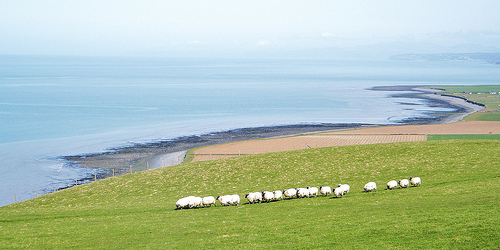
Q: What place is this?
A: It is an ocean.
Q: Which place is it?
A: It is an ocean.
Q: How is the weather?
A: It is cloudy.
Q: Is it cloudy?
A: Yes, it is cloudy.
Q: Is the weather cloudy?
A: Yes, it is cloudy.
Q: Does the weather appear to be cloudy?
A: Yes, it is cloudy.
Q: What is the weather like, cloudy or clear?
A: It is cloudy.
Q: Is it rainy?
A: No, it is cloudy.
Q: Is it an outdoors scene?
A: Yes, it is outdoors.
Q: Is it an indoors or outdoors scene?
A: It is outdoors.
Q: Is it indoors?
A: No, it is outdoors.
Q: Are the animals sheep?
A: Yes, all the animals are sheep.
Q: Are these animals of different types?
A: No, all the animals are sheep.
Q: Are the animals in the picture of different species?
A: No, all the animals are sheep.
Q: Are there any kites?
A: No, there are no kites.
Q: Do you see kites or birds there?
A: No, there are no kites or birds.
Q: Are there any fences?
A: Yes, there is a fence.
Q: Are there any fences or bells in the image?
A: Yes, there is a fence.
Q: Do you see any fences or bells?
A: Yes, there is a fence.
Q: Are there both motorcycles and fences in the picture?
A: No, there is a fence but no motorcycles.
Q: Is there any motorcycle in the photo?
A: No, there are no motorcycles.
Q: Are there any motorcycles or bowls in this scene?
A: No, there are no motorcycles or bowls.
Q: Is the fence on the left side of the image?
A: Yes, the fence is on the left of the image.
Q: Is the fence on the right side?
A: No, the fence is on the left of the image.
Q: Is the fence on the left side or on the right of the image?
A: The fence is on the left of the image.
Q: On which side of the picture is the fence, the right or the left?
A: The fence is on the left of the image.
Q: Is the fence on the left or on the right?
A: The fence is on the left of the image.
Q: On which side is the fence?
A: The fence is on the left of the image.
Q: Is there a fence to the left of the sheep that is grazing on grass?
A: Yes, there is a fence to the left of the sheep.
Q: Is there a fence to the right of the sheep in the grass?
A: No, the fence is to the left of the sheep.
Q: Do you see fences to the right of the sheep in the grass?
A: No, the fence is to the left of the sheep.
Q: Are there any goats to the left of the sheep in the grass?
A: No, there is a fence to the left of the sheep.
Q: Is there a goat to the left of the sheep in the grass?
A: No, there is a fence to the left of the sheep.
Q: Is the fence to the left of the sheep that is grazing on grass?
A: Yes, the fence is to the left of the sheep.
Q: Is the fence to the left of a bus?
A: No, the fence is to the left of the sheep.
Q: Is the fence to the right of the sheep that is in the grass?
A: No, the fence is to the left of the sheep.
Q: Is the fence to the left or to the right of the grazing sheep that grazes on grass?
A: The fence is to the left of the sheep.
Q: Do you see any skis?
A: No, there are no skis.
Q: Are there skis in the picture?
A: No, there are no skis.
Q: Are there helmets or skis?
A: No, there are no skis or helmets.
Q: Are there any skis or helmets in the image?
A: No, there are no skis or helmets.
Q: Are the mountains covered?
A: Yes, the mountains are covered.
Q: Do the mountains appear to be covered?
A: Yes, the mountains are covered.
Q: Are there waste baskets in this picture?
A: No, there are no waste baskets.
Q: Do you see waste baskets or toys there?
A: No, there are no waste baskets or toys.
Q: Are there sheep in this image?
A: Yes, there is a sheep.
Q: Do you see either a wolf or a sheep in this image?
A: Yes, there is a sheep.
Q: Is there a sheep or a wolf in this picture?
A: Yes, there is a sheep.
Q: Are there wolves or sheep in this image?
A: Yes, there is a sheep.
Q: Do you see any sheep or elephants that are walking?
A: Yes, the sheep is walking.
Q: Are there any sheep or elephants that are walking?
A: Yes, the sheep is walking.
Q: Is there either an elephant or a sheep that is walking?
A: Yes, the sheep is walking.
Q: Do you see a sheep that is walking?
A: Yes, there is a sheep that is walking.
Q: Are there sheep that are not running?
A: Yes, there is a sheep that is walking.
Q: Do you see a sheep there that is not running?
A: Yes, there is a sheep that is walking .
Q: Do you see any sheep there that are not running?
A: Yes, there is a sheep that is walking .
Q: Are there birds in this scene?
A: No, there are no birds.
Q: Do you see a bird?
A: No, there are no birds.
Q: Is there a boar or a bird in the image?
A: No, there are no birds or boars.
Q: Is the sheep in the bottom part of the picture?
A: Yes, the sheep is in the bottom of the image.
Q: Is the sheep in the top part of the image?
A: No, the sheep is in the bottom of the image.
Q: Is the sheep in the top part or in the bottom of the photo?
A: The sheep is in the bottom of the image.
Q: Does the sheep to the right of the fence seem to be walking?
A: Yes, the sheep is walking.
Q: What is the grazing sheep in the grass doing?
A: The sheep is walking.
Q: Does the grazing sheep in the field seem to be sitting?
A: No, the sheep is walking.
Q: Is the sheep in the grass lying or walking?
A: The sheep is walking.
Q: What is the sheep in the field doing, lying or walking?
A: The sheep is walking.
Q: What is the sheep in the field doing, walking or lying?
A: The sheep is walking.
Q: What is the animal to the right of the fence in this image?
A: The animal is a sheep.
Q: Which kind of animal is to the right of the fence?
A: The animal is a sheep.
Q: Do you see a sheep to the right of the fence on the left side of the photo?
A: Yes, there is a sheep to the right of the fence.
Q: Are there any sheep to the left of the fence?
A: No, the sheep is to the right of the fence.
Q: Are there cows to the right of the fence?
A: No, there is a sheep to the right of the fence.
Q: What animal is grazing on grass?
A: The sheep is grazing on grass.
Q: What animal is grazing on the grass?
A: The sheep is grazing on grass.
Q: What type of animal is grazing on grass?
A: The animal is a sheep.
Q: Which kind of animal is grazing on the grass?
A: The animal is a sheep.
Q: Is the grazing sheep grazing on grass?
A: Yes, the sheep is grazing on grass.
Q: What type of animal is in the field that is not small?
A: The animal is a sheep.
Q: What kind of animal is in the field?
A: The animal is a sheep.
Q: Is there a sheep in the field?
A: Yes, there is a sheep in the field.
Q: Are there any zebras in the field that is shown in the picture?
A: No, there is a sheep in the field.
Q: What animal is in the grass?
A: The animal is a sheep.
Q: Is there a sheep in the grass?
A: Yes, there is a sheep in the grass.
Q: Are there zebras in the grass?
A: No, there is a sheep in the grass.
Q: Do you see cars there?
A: No, there are no cars.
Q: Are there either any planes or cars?
A: No, there are no cars or planes.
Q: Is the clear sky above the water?
A: Yes, the sky is above the water.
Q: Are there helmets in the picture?
A: No, there are no helmets.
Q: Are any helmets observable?
A: No, there are no helmets.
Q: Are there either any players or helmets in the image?
A: No, there are no helmets or players.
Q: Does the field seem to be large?
A: Yes, the field is large.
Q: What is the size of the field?
A: The field is large.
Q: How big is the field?
A: The field is large.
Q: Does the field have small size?
A: No, the field is large.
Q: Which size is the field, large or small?
A: The field is large.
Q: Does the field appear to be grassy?
A: Yes, the field is grassy.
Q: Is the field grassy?
A: Yes, the field is grassy.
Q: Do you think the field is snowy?
A: No, the field is grassy.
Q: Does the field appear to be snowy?
A: No, the field is grassy.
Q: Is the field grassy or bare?
A: The field is grassy.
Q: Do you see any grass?
A: Yes, there is grass.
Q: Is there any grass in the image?
A: Yes, there is grass.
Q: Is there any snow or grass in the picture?
A: Yes, there is grass.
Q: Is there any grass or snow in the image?
A: Yes, there is grass.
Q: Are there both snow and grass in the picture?
A: No, there is grass but no snow.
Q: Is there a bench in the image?
A: No, there are no benches.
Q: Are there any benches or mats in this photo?
A: No, there are no benches or mats.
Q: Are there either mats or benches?
A: No, there are no benches or mats.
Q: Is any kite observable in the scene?
A: No, there are no kites.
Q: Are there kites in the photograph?
A: No, there are no kites.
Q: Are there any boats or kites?
A: No, there are no kites or boats.